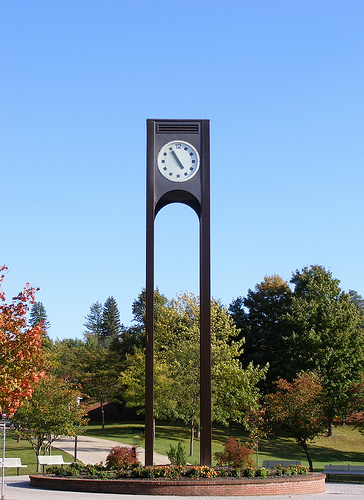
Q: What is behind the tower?
A: Trees.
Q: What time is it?
A: 4:55.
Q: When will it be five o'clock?
A: In five minutes.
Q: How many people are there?
A: None.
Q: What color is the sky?
A: Blue.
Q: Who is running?
A: No one.